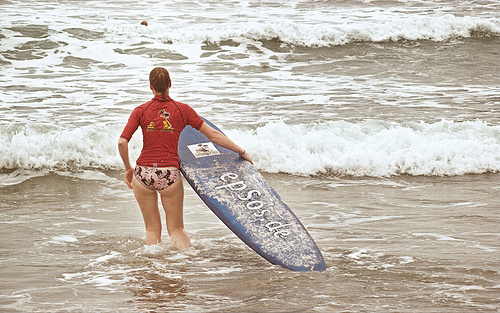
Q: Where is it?
A: This is at the ocean.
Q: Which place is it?
A: It is an ocean.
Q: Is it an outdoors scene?
A: Yes, it is outdoors.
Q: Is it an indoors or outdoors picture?
A: It is outdoors.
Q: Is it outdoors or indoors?
A: It is outdoors.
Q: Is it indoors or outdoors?
A: It is outdoors.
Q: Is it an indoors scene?
A: No, it is outdoors.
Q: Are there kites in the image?
A: No, there are no kites.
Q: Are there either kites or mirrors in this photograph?
A: No, there are no kites or mirrors.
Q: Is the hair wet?
A: Yes, the hair is wet.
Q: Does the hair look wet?
A: Yes, the hair is wet.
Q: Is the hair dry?
A: No, the hair is wet.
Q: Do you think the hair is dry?
A: No, the hair is wet.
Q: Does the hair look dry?
A: No, the hair is wet.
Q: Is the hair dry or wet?
A: The hair is wet.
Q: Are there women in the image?
A: Yes, there is a woman.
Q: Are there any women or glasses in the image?
A: Yes, there is a woman.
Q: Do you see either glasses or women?
A: Yes, there is a woman.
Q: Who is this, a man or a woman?
A: This is a woman.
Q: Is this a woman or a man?
A: This is a woman.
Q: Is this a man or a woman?
A: This is a woman.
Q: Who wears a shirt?
A: The woman wears a shirt.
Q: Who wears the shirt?
A: The woman wears a shirt.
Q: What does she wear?
A: The woman wears a shirt.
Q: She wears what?
A: The woman wears a shirt.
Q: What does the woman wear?
A: The woman wears a shirt.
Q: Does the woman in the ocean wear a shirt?
A: Yes, the woman wears a shirt.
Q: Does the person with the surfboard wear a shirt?
A: Yes, the woman wears a shirt.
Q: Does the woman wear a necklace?
A: No, the woman wears a shirt.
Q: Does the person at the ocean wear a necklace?
A: No, the woman wears a shirt.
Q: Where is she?
A: The woman is at the ocean.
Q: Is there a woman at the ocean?
A: Yes, there is a woman at the ocean.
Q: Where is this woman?
A: The woman is in the ocean.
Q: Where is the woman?
A: The woman is in the ocean.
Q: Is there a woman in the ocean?
A: Yes, there is a woman in the ocean.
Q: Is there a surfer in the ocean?
A: No, there is a woman in the ocean.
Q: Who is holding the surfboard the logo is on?
A: The woman is holding the surfboard.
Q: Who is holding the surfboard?
A: The woman is holding the surfboard.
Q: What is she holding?
A: The woman is holding the surfboard.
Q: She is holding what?
A: The woman is holding the surfboard.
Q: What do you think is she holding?
A: The woman is holding the surfboard.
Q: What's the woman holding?
A: The woman is holding the surfboard.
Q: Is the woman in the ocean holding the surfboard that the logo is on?
A: Yes, the woman is holding the surf board.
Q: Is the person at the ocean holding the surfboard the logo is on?
A: Yes, the woman is holding the surf board.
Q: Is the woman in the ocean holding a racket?
A: No, the woman is holding the surf board.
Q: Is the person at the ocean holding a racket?
A: No, the woman is holding the surf board.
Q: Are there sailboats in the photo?
A: No, there are no sailboats.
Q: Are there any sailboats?
A: No, there are no sailboats.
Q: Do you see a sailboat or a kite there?
A: No, there are no sailboats or kites.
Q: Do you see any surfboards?
A: Yes, there is a surfboard.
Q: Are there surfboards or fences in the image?
A: Yes, there is a surfboard.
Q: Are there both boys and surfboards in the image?
A: No, there is a surfboard but no boys.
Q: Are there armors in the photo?
A: No, there are no armors.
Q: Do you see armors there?
A: No, there are no armors.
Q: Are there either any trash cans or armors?
A: No, there are no armors or trash cans.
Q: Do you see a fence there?
A: No, there are no fences.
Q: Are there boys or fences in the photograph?
A: No, there are no fences or boys.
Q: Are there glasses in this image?
A: No, there are no glasses.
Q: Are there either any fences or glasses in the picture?
A: No, there are no glasses or fences.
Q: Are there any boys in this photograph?
A: No, there are no boys.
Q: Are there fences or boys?
A: No, there are no boys or fences.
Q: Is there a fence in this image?
A: No, there are no fences.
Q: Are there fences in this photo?
A: No, there are no fences.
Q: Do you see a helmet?
A: No, there are no helmets.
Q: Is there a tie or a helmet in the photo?
A: No, there are no helmets or ties.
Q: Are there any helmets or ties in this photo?
A: No, there are no helmets or ties.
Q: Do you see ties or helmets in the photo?
A: No, there are no helmets or ties.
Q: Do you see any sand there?
A: Yes, there is sand.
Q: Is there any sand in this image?
A: Yes, there is sand.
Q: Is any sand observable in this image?
A: Yes, there is sand.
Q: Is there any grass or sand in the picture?
A: Yes, there is sand.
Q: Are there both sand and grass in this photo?
A: No, there is sand but no grass.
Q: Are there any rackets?
A: No, there are no rackets.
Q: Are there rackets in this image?
A: No, there are no rackets.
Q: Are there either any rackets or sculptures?
A: No, there are no rackets or sculptures.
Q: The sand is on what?
A: The sand is on the surfboard.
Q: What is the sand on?
A: The sand is on the surfboard.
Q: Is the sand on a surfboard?
A: Yes, the sand is on a surfboard.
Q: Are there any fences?
A: No, there are no fences.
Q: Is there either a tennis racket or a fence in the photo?
A: No, there are no fences or rackets.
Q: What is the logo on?
A: The logo is on the surfboard.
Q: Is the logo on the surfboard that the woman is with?
A: Yes, the logo is on the surfboard.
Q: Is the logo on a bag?
A: No, the logo is on the surfboard.